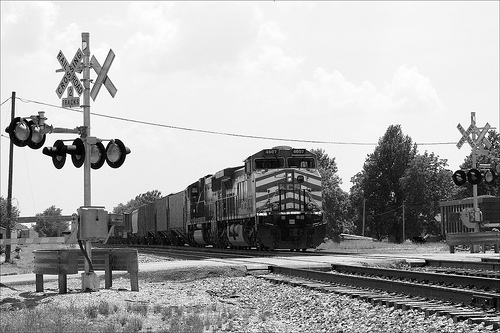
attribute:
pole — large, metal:
[71, 30, 100, 290]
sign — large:
[54, 46, 84, 101]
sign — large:
[89, 51, 118, 98]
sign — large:
[457, 124, 473, 147]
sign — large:
[476, 119, 491, 149]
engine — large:
[208, 147, 328, 247]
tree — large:
[345, 119, 457, 240]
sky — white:
[0, 1, 485, 120]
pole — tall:
[7, 92, 13, 240]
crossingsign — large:
[453, 123, 497, 165]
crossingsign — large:
[55, 47, 116, 100]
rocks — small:
[212, 269, 281, 311]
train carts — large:
[146, 193, 220, 231]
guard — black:
[259, 211, 353, 243]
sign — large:
[451, 106, 491, 186]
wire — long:
[11, 89, 499, 174]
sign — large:
[54, 48, 115, 100]